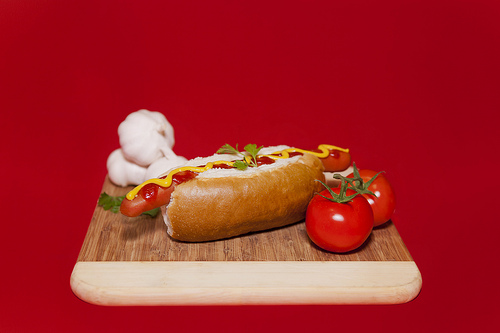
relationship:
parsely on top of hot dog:
[217, 142, 264, 170] [120, 144, 351, 242]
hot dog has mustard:
[120, 144, 351, 242] [124, 143, 350, 200]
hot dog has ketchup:
[120, 144, 351, 242] [141, 148, 340, 207]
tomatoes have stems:
[306, 164, 396, 253] [317, 161, 383, 204]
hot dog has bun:
[120, 144, 351, 242] [159, 143, 325, 243]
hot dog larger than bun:
[120, 144, 351, 242] [159, 143, 325, 243]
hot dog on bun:
[120, 144, 351, 242] [159, 143, 325, 243]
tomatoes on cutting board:
[306, 164, 396, 253] [70, 165, 423, 305]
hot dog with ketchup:
[120, 144, 351, 242] [141, 148, 340, 207]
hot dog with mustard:
[120, 144, 351, 242] [124, 143, 350, 200]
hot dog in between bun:
[120, 144, 351, 242] [159, 143, 325, 243]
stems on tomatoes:
[317, 161, 383, 204] [306, 164, 396, 253]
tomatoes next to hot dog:
[306, 164, 396, 253] [120, 144, 351, 242]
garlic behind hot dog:
[107, 108, 189, 186] [120, 144, 351, 242]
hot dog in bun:
[120, 144, 351, 242] [159, 143, 325, 243]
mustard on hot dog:
[124, 143, 350, 200] [120, 144, 351, 242]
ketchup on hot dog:
[141, 148, 340, 207] [120, 144, 351, 242]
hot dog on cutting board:
[120, 144, 351, 242] [70, 165, 423, 305]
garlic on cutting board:
[107, 108, 189, 186] [70, 165, 423, 305]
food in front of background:
[107, 107, 396, 254] [1, 0, 500, 332]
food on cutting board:
[107, 107, 396, 254] [70, 165, 423, 305]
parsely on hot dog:
[217, 142, 264, 170] [120, 144, 351, 242]